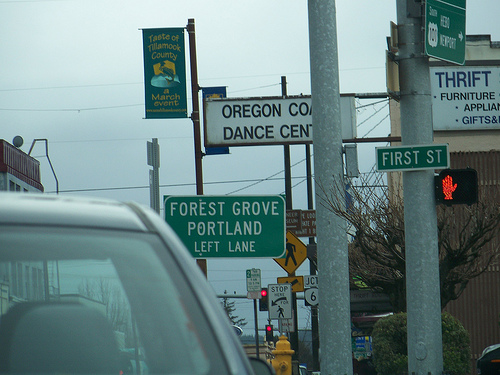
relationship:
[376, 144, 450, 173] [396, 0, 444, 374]
sign on pole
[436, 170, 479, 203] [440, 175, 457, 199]
sign with hand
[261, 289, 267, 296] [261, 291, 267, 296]
light on light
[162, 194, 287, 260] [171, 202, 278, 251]
sign with words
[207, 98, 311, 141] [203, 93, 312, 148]
sign on pole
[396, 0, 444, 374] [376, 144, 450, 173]
pole holding sign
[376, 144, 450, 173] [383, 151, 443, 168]
sign saying first st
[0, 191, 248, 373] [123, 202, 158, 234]
car with slit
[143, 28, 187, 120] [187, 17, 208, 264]
flag on pole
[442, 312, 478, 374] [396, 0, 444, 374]
bush behind pole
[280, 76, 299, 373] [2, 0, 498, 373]
pole in area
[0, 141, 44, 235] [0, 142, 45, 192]
top of building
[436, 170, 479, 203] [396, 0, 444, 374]
signal on pole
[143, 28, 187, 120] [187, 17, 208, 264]
sign on pole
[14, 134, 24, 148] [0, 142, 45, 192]
dish on building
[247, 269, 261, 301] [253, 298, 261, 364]
sign on pole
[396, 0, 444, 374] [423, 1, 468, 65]
pole with sign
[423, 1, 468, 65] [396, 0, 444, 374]
sign on pole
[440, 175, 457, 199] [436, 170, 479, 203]
hand meaning don't walk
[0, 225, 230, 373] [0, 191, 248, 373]
window of car